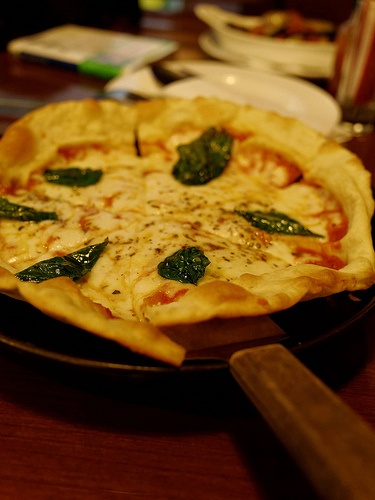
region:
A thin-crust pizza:
[3, 1, 373, 346]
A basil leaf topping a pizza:
[159, 221, 215, 287]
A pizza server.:
[139, 298, 372, 498]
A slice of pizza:
[140, 215, 360, 321]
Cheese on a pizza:
[139, 206, 232, 244]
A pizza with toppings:
[5, 109, 366, 310]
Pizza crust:
[17, 273, 344, 356]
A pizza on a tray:
[0, 108, 374, 390]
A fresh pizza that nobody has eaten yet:
[5, 104, 371, 355]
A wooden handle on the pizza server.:
[226, 342, 370, 480]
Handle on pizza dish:
[237, 358, 344, 461]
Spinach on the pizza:
[157, 245, 210, 284]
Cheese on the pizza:
[115, 191, 203, 226]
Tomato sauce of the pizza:
[315, 250, 340, 266]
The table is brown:
[62, 441, 138, 482]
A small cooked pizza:
[2, 108, 331, 297]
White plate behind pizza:
[226, 77, 302, 102]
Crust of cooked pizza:
[180, 290, 299, 312]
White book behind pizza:
[24, 34, 165, 61]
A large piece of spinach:
[171, 136, 237, 180]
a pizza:
[3, 105, 366, 332]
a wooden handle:
[238, 347, 366, 485]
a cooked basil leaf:
[161, 240, 206, 287]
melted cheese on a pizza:
[114, 195, 141, 221]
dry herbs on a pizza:
[172, 192, 210, 222]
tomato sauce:
[324, 193, 345, 241]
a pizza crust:
[43, 99, 148, 134]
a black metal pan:
[3, 322, 78, 382]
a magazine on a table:
[18, 16, 174, 82]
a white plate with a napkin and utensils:
[151, 52, 335, 110]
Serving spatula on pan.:
[152, 288, 267, 432]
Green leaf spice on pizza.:
[154, 228, 225, 309]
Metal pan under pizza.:
[50, 287, 179, 382]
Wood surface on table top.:
[33, 340, 175, 465]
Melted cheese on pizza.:
[133, 215, 292, 309]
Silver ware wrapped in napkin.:
[128, 41, 295, 138]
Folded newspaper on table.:
[19, 17, 177, 76]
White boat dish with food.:
[194, 0, 343, 78]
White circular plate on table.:
[158, 45, 330, 135]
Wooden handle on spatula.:
[203, 330, 363, 468]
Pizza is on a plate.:
[0, 81, 370, 372]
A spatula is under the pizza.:
[142, 301, 373, 499]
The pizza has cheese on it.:
[59, 213, 322, 316]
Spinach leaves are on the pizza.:
[142, 231, 219, 288]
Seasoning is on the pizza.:
[123, 188, 271, 258]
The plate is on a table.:
[0, 376, 373, 498]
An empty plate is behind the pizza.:
[84, 45, 360, 142]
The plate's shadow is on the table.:
[1, 359, 248, 445]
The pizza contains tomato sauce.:
[281, 195, 352, 271]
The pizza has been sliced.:
[2, 87, 374, 371]